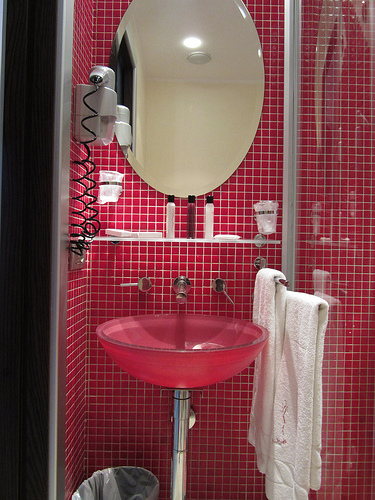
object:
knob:
[211, 276, 235, 309]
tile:
[207, 397, 215, 406]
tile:
[230, 406, 240, 417]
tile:
[103, 403, 112, 413]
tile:
[327, 358, 336, 370]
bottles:
[164, 192, 176, 238]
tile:
[297, 269, 306, 283]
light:
[181, 34, 203, 50]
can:
[70, 462, 165, 499]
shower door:
[280, 0, 374, 498]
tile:
[325, 430, 335, 440]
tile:
[328, 303, 338, 315]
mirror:
[107, 0, 269, 203]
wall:
[89, 2, 288, 499]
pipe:
[168, 389, 191, 499]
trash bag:
[67, 464, 162, 499]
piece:
[185, 407, 196, 430]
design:
[271, 399, 288, 447]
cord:
[66, 84, 101, 259]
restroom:
[0, 0, 375, 499]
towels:
[264, 282, 328, 500]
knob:
[119, 275, 152, 296]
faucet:
[168, 274, 193, 306]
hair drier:
[87, 63, 117, 94]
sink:
[95, 313, 271, 390]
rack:
[252, 256, 290, 290]